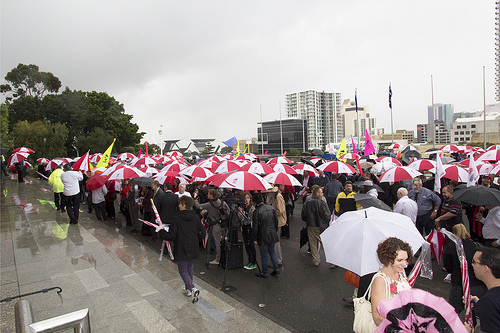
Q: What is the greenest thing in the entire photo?
A: Bunch of trees.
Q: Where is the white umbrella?
A: SE corner of the photo.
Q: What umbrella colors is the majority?
A: Red and white.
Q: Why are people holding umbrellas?
A: Raining.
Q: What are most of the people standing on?
A: Street.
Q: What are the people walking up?
A: Stairs.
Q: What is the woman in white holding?
A: White umbrella.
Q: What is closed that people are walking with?
A: Umbrellas.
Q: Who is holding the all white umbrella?
A: Woman in all white.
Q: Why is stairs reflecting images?
A: They are wet.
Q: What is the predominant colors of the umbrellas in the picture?
A: Red, and white.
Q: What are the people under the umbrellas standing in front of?
A: Building.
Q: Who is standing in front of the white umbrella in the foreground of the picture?
A: Female.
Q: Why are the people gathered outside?
A: Attending an event.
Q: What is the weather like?
A: Raining.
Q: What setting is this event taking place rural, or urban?
A: Urban.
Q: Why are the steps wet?
A: It's raining.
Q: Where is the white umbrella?
A: Right foreground.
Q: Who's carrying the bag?
A: The woman.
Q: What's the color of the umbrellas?
A: Red and white.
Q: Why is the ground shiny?
A: It rained.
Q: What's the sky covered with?
A: Rain clouds.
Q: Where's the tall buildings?
A: Background.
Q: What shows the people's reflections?
A: Wet sidewalk.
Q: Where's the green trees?
A: Background.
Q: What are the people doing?
A: Socializing.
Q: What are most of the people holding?
A: Umbrellas.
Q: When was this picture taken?
A: Daytime.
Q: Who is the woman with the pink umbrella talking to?
A: A man.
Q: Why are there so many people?
A: They are gathering for an event.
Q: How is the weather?
A: It is raining.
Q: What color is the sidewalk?
A: Grey.